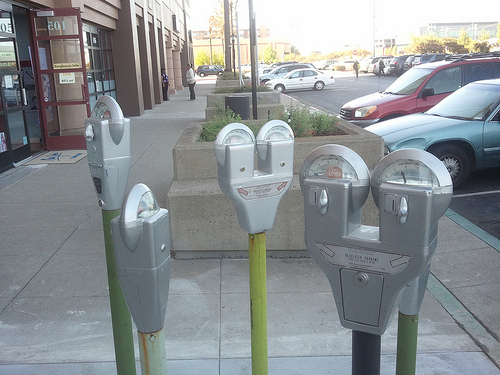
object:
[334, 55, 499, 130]
van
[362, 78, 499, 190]
car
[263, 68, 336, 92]
car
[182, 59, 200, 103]
woman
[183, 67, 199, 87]
sweater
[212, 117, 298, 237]
meter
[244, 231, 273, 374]
pole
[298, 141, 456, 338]
meter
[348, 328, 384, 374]
pole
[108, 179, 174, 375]
meter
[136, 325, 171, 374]
pole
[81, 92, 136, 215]
meter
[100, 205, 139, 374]
pole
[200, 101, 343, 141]
plants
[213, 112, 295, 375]
planter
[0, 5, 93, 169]
door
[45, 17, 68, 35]
number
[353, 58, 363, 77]
man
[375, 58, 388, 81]
person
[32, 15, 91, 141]
glass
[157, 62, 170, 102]
women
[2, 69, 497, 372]
sidewalk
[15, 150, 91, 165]
mat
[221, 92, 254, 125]
trash can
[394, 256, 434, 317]
meter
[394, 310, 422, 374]
pole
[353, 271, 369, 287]
lock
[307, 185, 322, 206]
slot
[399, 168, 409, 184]
arrow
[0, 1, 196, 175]
building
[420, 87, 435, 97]
mirror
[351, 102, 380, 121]
headlight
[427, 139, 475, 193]
wheel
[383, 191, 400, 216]
slot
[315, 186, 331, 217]
knob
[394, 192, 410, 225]
knob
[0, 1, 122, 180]
business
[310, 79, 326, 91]
wheel